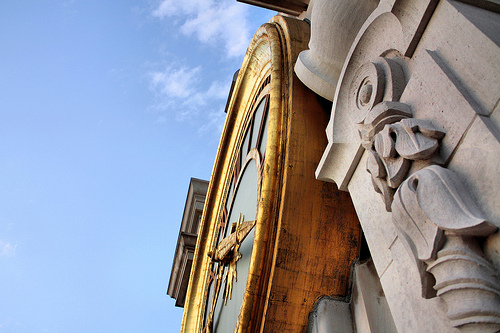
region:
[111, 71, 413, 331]
Clock on the building.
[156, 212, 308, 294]
Hands on the clock.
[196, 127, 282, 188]
Numbers on the clock.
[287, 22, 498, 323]
Scroll on the building.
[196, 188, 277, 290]
Gold hands on the clock.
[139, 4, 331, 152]
Clouds in the sky.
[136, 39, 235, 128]
White clouds in the sky.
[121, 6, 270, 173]
Blue sky with white clouds.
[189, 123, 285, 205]
Gold numbers on the clock.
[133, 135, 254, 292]
Tower against the sky.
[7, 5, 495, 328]
clock on a building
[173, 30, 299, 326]
gold-colored trim around clock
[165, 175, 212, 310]
top portion of building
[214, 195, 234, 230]
brass-colored number on clock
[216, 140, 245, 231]
Roman numerals on clock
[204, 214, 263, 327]
brass-colored clock hands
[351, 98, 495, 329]
trim on outside building wall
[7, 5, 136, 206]
patch of clear blue sky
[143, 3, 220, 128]
white clouds in sky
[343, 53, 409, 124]
multiple circles carving on building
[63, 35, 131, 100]
blue sky's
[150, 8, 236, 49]
small white clouds in blue sky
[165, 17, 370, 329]
large clock on side of building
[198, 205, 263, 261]
large golden dial on clock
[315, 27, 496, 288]
designs on side of concrete building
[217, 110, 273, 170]
numeric numbers of clock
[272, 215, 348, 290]
rim sides of golden clock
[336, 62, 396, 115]
circle cement design on building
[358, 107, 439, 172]
small wave design on side of concrete building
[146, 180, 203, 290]
top edge of concrete building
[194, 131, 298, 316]
yellow clock on building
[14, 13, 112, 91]
white clouds in blue sky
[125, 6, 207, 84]
white clouds in blue sky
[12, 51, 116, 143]
white clouds in blue sky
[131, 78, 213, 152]
white clouds in blue sky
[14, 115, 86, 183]
white clouds in blue sky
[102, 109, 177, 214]
white clouds in blue sky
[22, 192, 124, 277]
white clouds in blue sky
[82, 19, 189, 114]
white clouds in blue sky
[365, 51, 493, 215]
tan and white building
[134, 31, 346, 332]
clock on the side of the building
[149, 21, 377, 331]
gold and white clock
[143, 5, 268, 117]
white clouds in the sky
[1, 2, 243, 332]
sky is bright blue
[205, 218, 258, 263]
gold clock hand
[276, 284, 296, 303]
black mark on the clock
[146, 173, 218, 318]
roof of the building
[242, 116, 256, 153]
gold line on the clock face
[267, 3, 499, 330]
concrete building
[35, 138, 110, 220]
patch of sky with no clouds